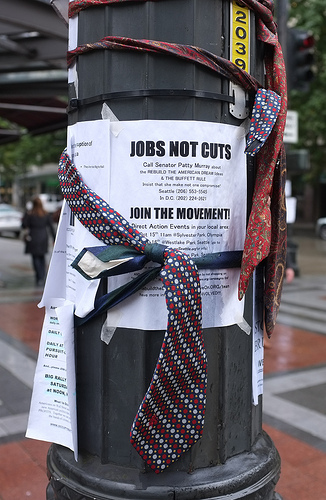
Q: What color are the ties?
A: Red.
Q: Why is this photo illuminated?
A: Sunlight.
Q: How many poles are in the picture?
A: One.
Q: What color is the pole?
A: Black.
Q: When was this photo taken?
A: During the day.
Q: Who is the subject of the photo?
A: The poster.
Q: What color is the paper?
A: White.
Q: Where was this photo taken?
A: On the street.